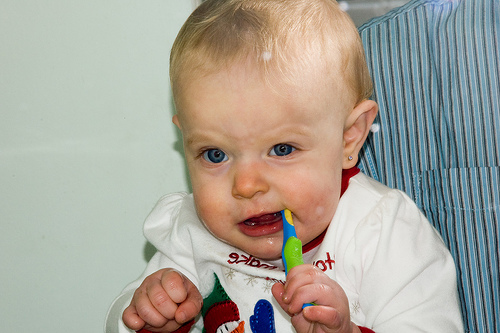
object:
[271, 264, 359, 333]
left hand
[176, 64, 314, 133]
forehead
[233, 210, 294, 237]
mouth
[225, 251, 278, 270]
writing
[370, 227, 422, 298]
cloth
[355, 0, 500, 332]
cover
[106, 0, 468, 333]
baby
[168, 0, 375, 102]
hair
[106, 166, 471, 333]
shirt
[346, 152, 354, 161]
earring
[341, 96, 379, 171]
ear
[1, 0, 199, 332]
wall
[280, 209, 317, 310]
object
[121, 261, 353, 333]
two hands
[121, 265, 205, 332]
baby's hand